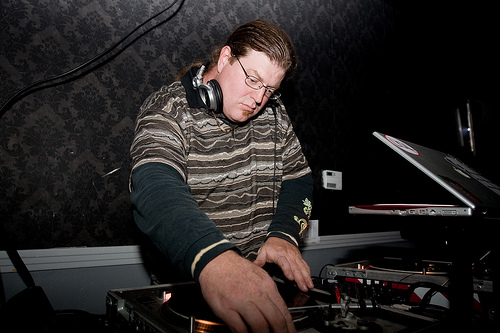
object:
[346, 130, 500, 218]
laptop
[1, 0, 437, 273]
wall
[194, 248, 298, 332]
hand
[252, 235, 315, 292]
hand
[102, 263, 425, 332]
record player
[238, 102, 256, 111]
mouth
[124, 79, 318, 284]
shirt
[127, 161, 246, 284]
sleeve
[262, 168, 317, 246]
sleeve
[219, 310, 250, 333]
finger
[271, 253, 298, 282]
finger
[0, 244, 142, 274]
trim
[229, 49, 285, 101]
eyeglasses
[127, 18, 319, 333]
man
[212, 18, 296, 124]
head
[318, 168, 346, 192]
control switch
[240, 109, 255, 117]
goatee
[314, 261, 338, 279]
wires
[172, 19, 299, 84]
brown hair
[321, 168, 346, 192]
panel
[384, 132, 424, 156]
sticker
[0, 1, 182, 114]
wire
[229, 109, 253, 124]
chin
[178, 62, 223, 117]
headphones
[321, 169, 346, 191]
box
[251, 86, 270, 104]
nose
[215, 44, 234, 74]
ear